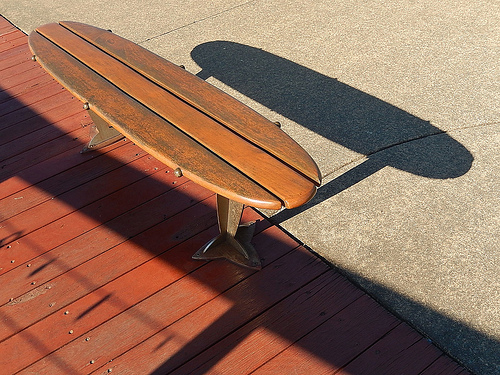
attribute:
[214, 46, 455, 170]
shadow — black, bench, board, dark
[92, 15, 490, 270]
ground — concrete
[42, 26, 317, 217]
bench — surfboard, long, orange, wooden, oblong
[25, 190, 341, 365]
walkway — red, wooden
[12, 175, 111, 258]
boards — red, wood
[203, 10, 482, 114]
walkway — concrete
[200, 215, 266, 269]
leg — metal, brown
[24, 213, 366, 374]
sidewalk — wooden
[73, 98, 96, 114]
screws — bronze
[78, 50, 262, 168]
surfboard — wooden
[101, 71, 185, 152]
deck — wooden